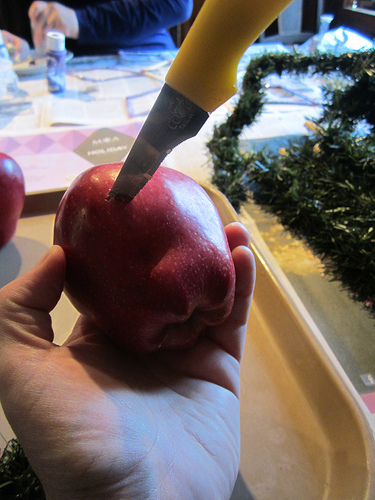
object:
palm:
[44, 340, 242, 474]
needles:
[207, 46, 373, 260]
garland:
[208, 46, 375, 200]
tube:
[45, 31, 67, 95]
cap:
[46, 31, 65, 51]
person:
[23, 0, 196, 55]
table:
[0, 26, 374, 186]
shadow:
[0, 234, 34, 289]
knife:
[109, 0, 296, 204]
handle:
[164, 0, 297, 115]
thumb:
[0, 244, 64, 413]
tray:
[0, 174, 373, 498]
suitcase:
[46, 155, 238, 360]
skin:
[103, 190, 192, 260]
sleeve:
[75, 0, 193, 36]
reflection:
[156, 422, 206, 467]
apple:
[53, 161, 237, 352]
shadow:
[74, 332, 190, 394]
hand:
[0, 221, 256, 500]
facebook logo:
[359, 370, 373, 388]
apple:
[0, 153, 25, 251]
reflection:
[166, 172, 227, 253]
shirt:
[73, 0, 194, 49]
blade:
[110, 82, 212, 199]